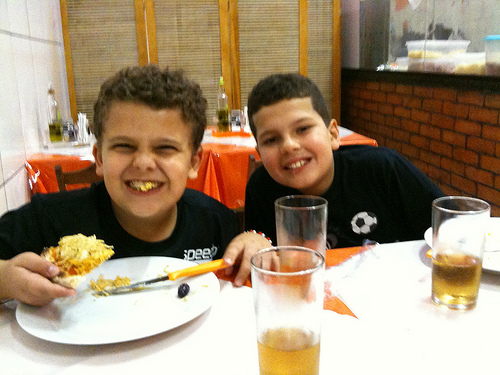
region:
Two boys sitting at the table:
[340, 76, 499, 219]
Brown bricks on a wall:
[339, 71, 498, 220]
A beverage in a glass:
[425, 191, 490, 313]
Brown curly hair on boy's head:
[85, 57, 208, 155]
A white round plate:
[12, 252, 222, 348]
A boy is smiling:
[242, 71, 342, 191]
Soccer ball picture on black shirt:
[343, 206, 380, 237]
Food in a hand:
[10, 225, 116, 315]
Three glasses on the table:
[243, 190, 493, 372]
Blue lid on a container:
[481, 29, 499, 44]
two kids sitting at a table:
[1, 56, 472, 322]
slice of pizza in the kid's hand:
[41, 230, 116, 290]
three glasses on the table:
[248, 195, 493, 374]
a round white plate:
[11, 255, 221, 347]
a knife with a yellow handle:
[92, 258, 232, 300]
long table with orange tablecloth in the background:
[26, 111, 377, 212]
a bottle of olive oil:
[212, 74, 233, 136]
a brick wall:
[333, 69, 498, 216]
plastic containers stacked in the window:
[396, 30, 498, 76]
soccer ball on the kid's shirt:
[347, 210, 382, 235]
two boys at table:
[63, 95, 425, 276]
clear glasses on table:
[240, 189, 485, 361]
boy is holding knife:
[115, 236, 275, 306]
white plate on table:
[37, 256, 225, 348]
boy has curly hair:
[105, 41, 215, 145]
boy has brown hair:
[243, 71, 311, 126]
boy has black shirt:
[32, 173, 232, 265]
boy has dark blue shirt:
[236, 163, 447, 268]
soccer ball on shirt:
[337, 194, 402, 241]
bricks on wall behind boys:
[351, 84, 491, 187]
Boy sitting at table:
[224, 74, 456, 246]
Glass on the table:
[416, 181, 493, 318]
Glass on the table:
[268, 198, 343, 308]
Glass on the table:
[242, 235, 337, 373]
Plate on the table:
[8, 237, 230, 354]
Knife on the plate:
[92, 251, 239, 308]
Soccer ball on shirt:
[343, 203, 395, 238]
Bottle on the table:
[204, 70, 239, 141]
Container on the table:
[397, 23, 469, 76]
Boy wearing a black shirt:
[1, 55, 282, 305]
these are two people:
[98, 131, 455, 275]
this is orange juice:
[252, 325, 311, 370]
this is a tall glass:
[229, 272, 322, 367]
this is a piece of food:
[60, 229, 136, 309]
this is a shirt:
[35, 183, 112, 305]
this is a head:
[115, 51, 170, 183]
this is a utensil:
[119, 208, 177, 313]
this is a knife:
[98, 261, 230, 368]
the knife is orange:
[104, 248, 196, 350]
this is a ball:
[345, 217, 372, 256]